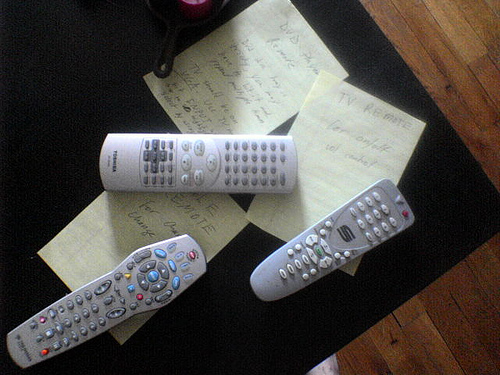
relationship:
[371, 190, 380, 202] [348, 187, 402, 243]
key on keyboard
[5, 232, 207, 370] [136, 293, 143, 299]
remote has button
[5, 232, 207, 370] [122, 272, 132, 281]
remote has button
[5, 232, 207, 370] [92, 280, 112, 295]
remote has button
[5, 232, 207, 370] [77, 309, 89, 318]
remote has button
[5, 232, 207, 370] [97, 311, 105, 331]
remote has button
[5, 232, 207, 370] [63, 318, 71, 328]
remote has button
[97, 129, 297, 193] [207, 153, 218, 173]
remote has button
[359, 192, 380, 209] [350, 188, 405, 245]
key on keyboard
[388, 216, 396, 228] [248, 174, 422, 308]
key on keyboard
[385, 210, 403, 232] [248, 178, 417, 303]
key on remote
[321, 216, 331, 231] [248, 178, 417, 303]
key on remote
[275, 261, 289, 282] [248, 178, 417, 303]
key on remote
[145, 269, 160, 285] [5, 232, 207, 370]
button on remote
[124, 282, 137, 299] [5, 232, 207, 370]
button on remote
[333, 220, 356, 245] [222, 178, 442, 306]
s on remote control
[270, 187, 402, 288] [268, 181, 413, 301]
buttons on remote